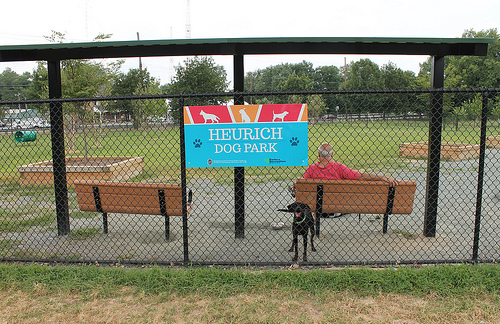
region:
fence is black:
[2, 82, 497, 270]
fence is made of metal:
[2, 97, 497, 269]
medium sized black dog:
[281, 200, 326, 269]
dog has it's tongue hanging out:
[281, 198, 318, 262]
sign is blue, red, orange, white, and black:
[181, 104, 317, 172]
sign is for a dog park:
[172, 105, 314, 175]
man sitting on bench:
[268, 135, 421, 232]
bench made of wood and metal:
[295, 144, 417, 234]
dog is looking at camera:
[272, 196, 319, 261]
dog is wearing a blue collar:
[277, 192, 317, 264]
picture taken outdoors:
[75, 70, 484, 256]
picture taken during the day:
[57, 44, 391, 256]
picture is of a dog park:
[57, 61, 483, 241]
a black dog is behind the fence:
[257, 162, 438, 296]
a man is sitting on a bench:
[302, 137, 411, 226]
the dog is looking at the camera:
[270, 194, 330, 274]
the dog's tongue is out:
[282, 190, 337, 242]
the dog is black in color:
[279, 195, 352, 273]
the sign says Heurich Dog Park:
[184, 121, 344, 181]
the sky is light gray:
[214, 20, 364, 52]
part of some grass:
[378, 271, 465, 321]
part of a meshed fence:
[289, 211, 335, 248]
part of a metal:
[471, 220, 484, 256]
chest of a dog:
[288, 220, 299, 232]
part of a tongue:
[292, 208, 306, 226]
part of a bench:
[344, 187, 374, 202]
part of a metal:
[316, 192, 326, 224]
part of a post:
[426, 185, 439, 212]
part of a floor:
[361, 232, 389, 244]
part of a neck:
[291, 222, 303, 236]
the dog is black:
[275, 192, 335, 276]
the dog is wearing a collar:
[286, 207, 313, 229]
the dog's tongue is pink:
[288, 211, 305, 222]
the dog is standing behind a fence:
[0, 81, 495, 270]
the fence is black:
[2, 99, 497, 275]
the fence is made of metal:
[3, 95, 497, 270]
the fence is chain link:
[2, 95, 498, 275]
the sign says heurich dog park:
[175, 101, 317, 171]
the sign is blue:
[174, 96, 311, 173]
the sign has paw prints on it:
[190, 137, 206, 157]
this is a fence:
[327, 105, 447, 229]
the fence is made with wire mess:
[329, 145, 388, 225]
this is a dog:
[286, 201, 318, 251]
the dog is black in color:
[296, 218, 311, 230]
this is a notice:
[184, 107, 306, 154]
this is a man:
[317, 142, 344, 177]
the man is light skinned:
[364, 173, 382, 180]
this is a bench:
[313, 182, 385, 207]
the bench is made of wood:
[328, 190, 373, 202]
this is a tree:
[174, 63, 222, 84]